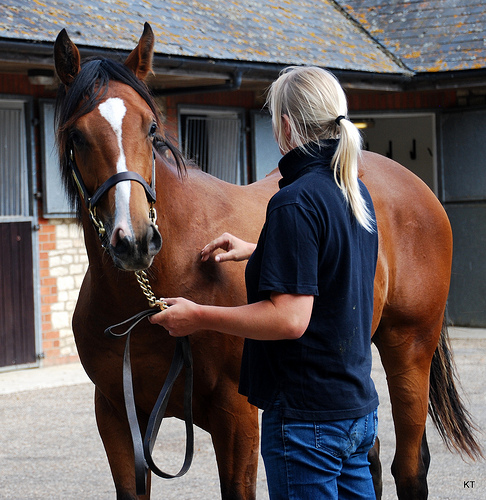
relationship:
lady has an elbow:
[150, 61, 384, 499] [260, 308, 315, 343]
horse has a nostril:
[50, 26, 485, 500] [142, 229, 164, 258]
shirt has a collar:
[238, 137, 384, 418] [272, 140, 350, 182]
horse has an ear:
[50, 26, 485, 500] [123, 18, 157, 85]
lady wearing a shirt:
[150, 61, 384, 499] [238, 137, 384, 418]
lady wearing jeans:
[150, 61, 384, 499] [257, 411, 382, 500]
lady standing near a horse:
[150, 61, 384, 499] [50, 26, 485, 500]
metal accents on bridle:
[84, 206, 111, 239] [64, 101, 163, 252]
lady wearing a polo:
[150, 61, 384, 499] [238, 137, 384, 418]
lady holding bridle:
[150, 61, 384, 499] [64, 101, 163, 252]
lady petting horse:
[150, 61, 384, 499] [50, 26, 485, 500]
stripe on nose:
[92, 93, 143, 241] [109, 181, 161, 264]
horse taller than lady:
[50, 26, 485, 500] [150, 61, 384, 499]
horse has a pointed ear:
[50, 26, 485, 500] [50, 22, 85, 88]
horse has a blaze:
[50, 26, 485, 500] [92, 93, 143, 241]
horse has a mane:
[50, 26, 485, 500] [46, 49, 202, 214]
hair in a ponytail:
[267, 61, 380, 235] [329, 112, 381, 235]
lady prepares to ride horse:
[150, 61, 384, 499] [50, 26, 485, 500]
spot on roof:
[401, 48, 422, 60] [2, 0, 486, 75]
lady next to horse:
[150, 61, 384, 499] [50, 26, 485, 500]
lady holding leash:
[150, 61, 384, 499] [105, 273, 213, 497]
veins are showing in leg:
[386, 364, 427, 431] [375, 318, 434, 499]